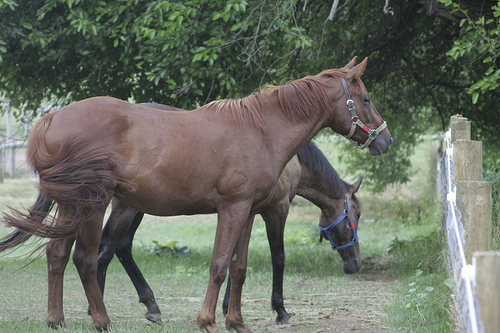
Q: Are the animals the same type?
A: Yes, all the animals are horses.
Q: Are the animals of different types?
A: No, all the animals are horses.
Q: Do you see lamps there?
A: No, there are no lamps.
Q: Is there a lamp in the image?
A: No, there are no lamps.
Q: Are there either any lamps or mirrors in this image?
A: No, there are no lamps or mirrors.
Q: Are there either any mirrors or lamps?
A: No, there are no lamps or mirrors.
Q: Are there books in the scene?
A: No, there are no books.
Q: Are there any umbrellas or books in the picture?
A: No, there are no books or umbrellas.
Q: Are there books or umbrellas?
A: No, there are no books or umbrellas.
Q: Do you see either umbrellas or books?
A: No, there are no books or umbrellas.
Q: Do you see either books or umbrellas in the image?
A: No, there are no books or umbrellas.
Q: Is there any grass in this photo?
A: Yes, there is grass.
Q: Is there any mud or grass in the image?
A: Yes, there is grass.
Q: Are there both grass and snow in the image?
A: No, there is grass but no snow.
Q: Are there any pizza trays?
A: No, there are no pizza trays.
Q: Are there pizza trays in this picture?
A: No, there are no pizza trays.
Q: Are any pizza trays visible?
A: No, there are no pizza trays.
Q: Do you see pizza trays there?
A: No, there are no pizza trays.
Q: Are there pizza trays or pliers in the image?
A: No, there are no pizza trays or pliers.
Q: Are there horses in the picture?
A: Yes, there is a horse.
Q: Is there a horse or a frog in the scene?
A: Yes, there is a horse.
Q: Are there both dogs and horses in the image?
A: No, there is a horse but no dogs.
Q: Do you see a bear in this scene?
A: No, there are no bears.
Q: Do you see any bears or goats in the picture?
A: No, there are no bears or goats.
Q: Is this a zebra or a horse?
A: This is a horse.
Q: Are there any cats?
A: No, there are no cats.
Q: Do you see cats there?
A: No, there are no cats.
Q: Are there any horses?
A: Yes, there is a horse.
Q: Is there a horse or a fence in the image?
A: Yes, there is a horse.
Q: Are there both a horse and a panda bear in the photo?
A: No, there is a horse but no panda bears.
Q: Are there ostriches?
A: No, there are no ostriches.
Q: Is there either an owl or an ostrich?
A: No, there are no ostriches or owls.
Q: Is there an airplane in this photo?
A: Yes, there is an airplane.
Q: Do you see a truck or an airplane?
A: Yes, there is an airplane.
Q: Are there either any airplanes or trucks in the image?
A: Yes, there is an airplane.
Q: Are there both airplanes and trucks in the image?
A: No, there is an airplane but no trucks.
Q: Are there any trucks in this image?
A: No, there are no trucks.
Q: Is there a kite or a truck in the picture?
A: No, there are no trucks or kites.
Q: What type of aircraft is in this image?
A: The aircraft is an airplane.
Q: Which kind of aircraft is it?
A: The aircraft is an airplane.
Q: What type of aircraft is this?
A: This is an airplane.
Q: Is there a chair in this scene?
A: No, there are no chairs.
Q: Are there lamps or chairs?
A: No, there are no chairs or lamps.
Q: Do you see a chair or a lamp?
A: No, there are no chairs or lamps.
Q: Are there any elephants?
A: No, there are no elephants.